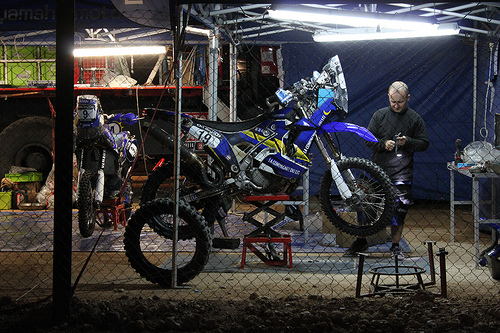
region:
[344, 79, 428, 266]
A man working on a motorcycle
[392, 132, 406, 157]
A light in the man's hand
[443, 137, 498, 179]
Supplies sitting on a shelf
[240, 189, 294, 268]
A red motorcycle stand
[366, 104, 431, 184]
A black shirt on the man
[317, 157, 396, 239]
The motorcycle's front tire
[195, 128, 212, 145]
Black numbers on the motorcycle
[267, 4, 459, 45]
Fluorescent lights in the ceiling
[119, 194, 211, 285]
A tire leaning against the fence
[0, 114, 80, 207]
A large tire in the background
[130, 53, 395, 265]
A motorbike in the photo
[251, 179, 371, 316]
A mesh wire in the photo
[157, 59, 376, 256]
A blue motorbike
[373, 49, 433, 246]
A person in the photo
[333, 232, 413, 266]
Black shoes on the legs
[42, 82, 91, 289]
A metal pole in the photo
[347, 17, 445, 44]
Lighting on the roof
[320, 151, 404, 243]
Bike tire in the picture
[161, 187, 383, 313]
A fence in the picture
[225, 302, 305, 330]
Rock pebbles in the photo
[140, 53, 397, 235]
blue motorcycle with a yellow stripe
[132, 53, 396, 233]
blue motorcycle on a jack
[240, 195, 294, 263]
red and black jack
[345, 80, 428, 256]
man in black repairing motorcycle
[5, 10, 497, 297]
chain link fence in front of motorcycle shopo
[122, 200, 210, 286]
black tire leaning against the fence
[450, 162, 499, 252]
metal table on the right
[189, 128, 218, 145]
number 19 on the motorcycle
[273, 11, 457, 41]
two fluorescent lights above man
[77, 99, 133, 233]
bike number 9 on the left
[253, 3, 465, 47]
overhead florescent lighting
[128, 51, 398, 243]
blue, yellow and white dirt motorcycle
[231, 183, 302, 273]
red and black motorcycle jack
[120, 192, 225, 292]
extra dirt motorcycle tire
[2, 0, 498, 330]
metal chain link fencing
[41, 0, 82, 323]
fence post in the shadows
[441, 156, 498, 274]
gray colored metal workshop table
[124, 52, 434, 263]
man with blonde hair working on dirt bike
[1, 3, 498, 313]
carport made into workshop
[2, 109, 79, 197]
large truck tire and heel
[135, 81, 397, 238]
blue and yellow motorcycle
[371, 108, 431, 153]
black cotton turtleneck shirt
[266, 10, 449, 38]
tube lights on ceiling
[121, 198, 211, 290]
black tire on fence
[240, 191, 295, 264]
black and white bike lift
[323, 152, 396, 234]
black tire on bike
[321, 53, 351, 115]
bug shield on bike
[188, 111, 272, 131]
black seat on bike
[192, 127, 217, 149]
number decal on bike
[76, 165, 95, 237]
rubber tire on bike